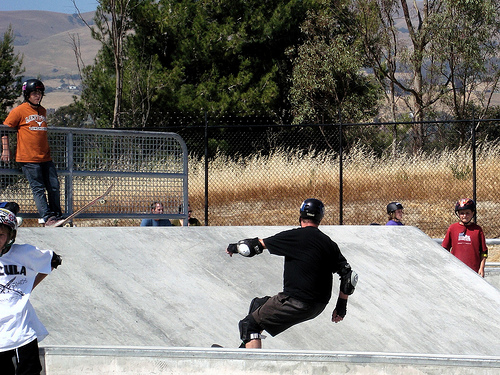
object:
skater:
[209, 197, 357, 349]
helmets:
[293, 197, 326, 224]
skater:
[0, 77, 69, 228]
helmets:
[19, 78, 47, 105]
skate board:
[48, 180, 118, 234]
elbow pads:
[232, 237, 263, 259]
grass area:
[2, 144, 497, 216]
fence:
[202, 122, 497, 239]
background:
[0, 0, 499, 375]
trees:
[280, 3, 496, 176]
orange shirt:
[2, 100, 55, 163]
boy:
[441, 197, 488, 284]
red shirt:
[439, 221, 489, 275]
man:
[0, 206, 62, 373]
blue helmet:
[0, 208, 20, 249]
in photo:
[0, 0, 498, 375]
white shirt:
[0, 241, 55, 351]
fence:
[1, 124, 196, 227]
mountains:
[0, 8, 118, 85]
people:
[137, 199, 173, 231]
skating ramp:
[12, 218, 499, 368]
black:
[265, 227, 347, 303]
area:
[5, 70, 496, 203]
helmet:
[450, 197, 477, 221]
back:
[3, 225, 67, 314]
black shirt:
[261, 224, 350, 309]